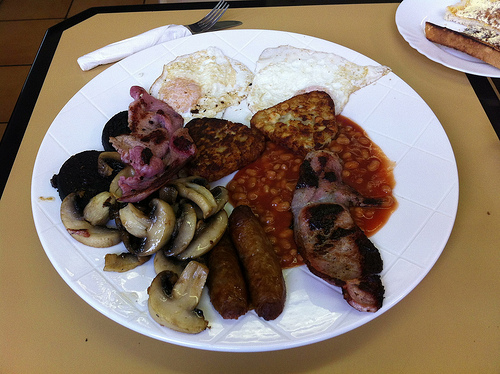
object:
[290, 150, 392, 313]
ham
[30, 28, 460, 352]
plate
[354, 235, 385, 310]
char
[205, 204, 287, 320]
sausages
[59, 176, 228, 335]
mushrooms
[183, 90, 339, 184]
hash browns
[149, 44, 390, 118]
eggs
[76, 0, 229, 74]
fork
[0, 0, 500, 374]
table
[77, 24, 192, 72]
napkin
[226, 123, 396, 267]
beans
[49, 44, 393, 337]
food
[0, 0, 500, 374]
photo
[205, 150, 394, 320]
meat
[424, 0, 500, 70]
bread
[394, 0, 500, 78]
plate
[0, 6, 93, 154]
edges